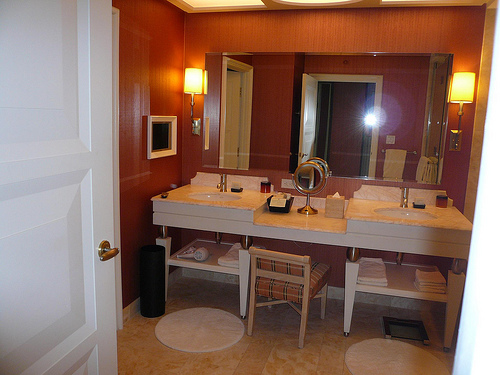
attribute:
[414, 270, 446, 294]
towels — white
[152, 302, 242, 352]
round rug — white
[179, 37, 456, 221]
mirror — round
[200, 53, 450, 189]
mirror — square, rectangular 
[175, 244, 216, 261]
hair — white 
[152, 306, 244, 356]
rug — circular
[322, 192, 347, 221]
tissue box — tan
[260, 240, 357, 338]
chair — tan 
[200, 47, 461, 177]
mirror — silver 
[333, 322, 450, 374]
rug — round 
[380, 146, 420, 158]
rack — silver 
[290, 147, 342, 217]
mirror — gold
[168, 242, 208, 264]
hair dryer — white 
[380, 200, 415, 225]
sink — double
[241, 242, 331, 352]
chair — small , wooden 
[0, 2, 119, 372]
door — gold , white 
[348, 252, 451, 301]
towels — White 